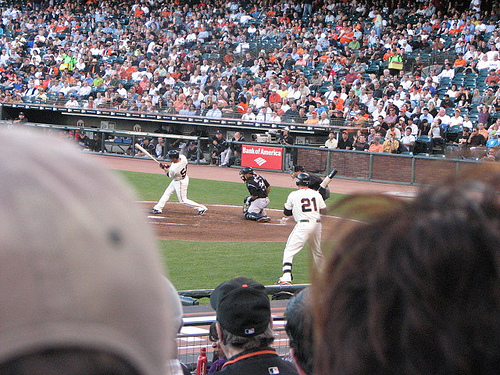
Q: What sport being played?
A: Baseball.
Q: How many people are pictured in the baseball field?
A: Four.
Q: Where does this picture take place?
A: Baseball stadium.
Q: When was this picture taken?
A: Daytime.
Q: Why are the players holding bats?
A: To hit the ball.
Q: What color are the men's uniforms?
A: White and black.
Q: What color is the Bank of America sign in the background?
A: Red.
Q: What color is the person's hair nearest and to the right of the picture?
A: Dark brown.